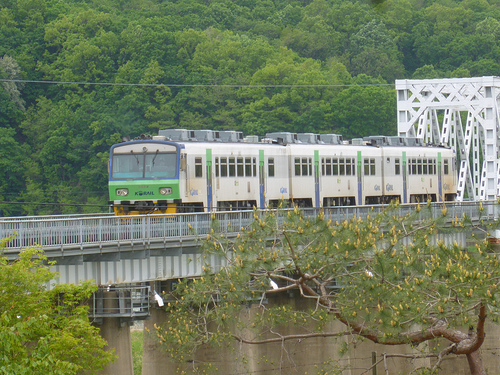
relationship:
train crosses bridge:
[108, 130, 458, 244] [2, 210, 446, 292]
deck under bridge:
[84, 281, 153, 321] [0, 197, 499, 260]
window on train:
[195, 156, 204, 176] [106, 134, 456, 220]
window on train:
[195, 156, 204, 176] [118, 102, 481, 200]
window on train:
[180, 140, 256, 176] [136, 115, 356, 200]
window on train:
[392, 157, 402, 177] [103, 125, 455, 221]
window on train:
[441, 152, 456, 179] [93, 126, 466, 229]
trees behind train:
[10, 24, 389, 139] [101, 121, 481, 207]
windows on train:
[183, 157, 456, 174] [101, 127, 477, 209]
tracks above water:
[1, 200, 498, 292] [3, 290, 499, 373]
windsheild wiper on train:
[148, 149, 158, 171] [103, 125, 455, 221]